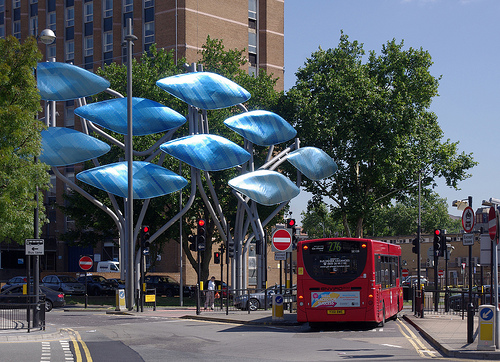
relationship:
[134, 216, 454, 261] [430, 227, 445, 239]
traffic lights lit up red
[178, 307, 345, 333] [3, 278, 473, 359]
shadow on ground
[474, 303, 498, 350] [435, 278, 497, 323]
white arrow on sign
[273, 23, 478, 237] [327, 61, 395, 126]
tree with leaves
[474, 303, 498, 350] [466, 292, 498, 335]
white arrow pointing down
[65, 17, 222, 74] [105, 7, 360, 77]
windows on building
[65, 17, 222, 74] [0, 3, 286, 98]
windows on a building